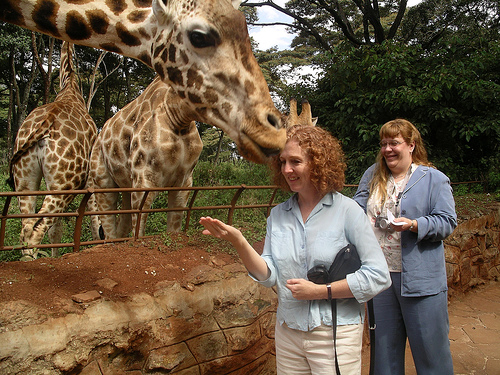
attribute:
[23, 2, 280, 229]
giraffe — big, tall, eating, skinny, looking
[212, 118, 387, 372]
woman — old, small, white, standing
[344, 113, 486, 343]
woman — standing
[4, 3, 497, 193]
trees —  brown, green, tall, wide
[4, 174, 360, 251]
fence — small, brown, short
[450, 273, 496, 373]
pathway —  cobblestone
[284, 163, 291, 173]
nose —  woman's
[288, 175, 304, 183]
mouth —  woman's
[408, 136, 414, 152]
ear —  woman's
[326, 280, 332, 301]
watch — wrist's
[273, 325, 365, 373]
pants —  white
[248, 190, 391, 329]
shirt —  light blue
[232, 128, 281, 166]
mouth —  giraffe's